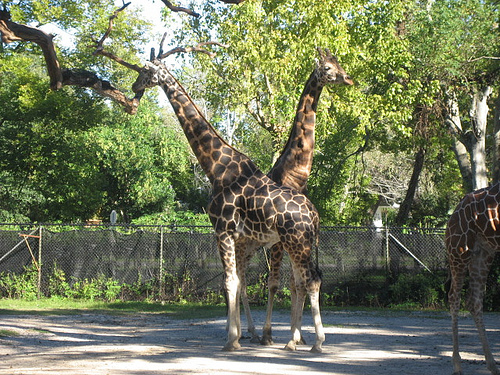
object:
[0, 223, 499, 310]
fence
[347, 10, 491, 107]
tree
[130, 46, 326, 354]
giraffes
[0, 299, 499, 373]
ground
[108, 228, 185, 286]
metal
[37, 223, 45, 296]
post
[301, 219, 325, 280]
tail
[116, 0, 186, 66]
sunlight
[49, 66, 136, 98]
branch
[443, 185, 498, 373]
giraffe